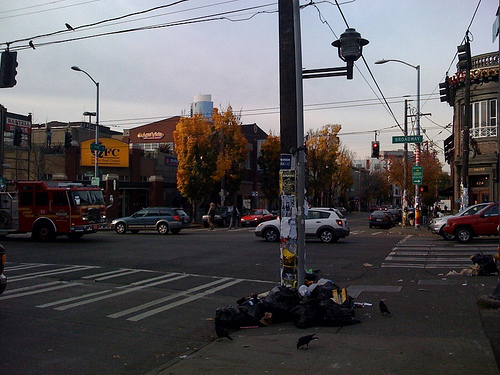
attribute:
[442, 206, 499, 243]
car — red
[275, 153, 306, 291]
ads — paper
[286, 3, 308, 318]
pole — electric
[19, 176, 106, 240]
truck — is big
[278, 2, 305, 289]
telephone pole — tall, brown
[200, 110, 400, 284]
tree — large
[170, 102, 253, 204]
leaves — brown, bunch 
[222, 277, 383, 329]
garbage — big